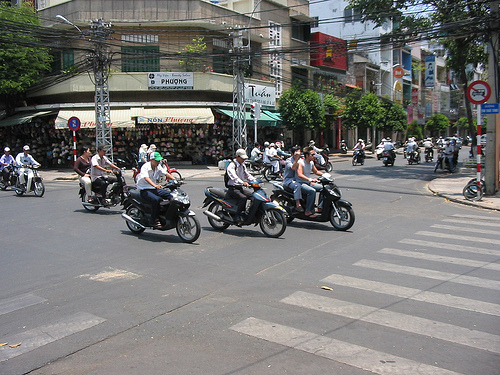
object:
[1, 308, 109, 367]
lines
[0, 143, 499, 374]
street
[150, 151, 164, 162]
hat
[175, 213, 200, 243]
wheel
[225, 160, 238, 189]
backpack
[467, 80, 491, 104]
sign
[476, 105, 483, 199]
pole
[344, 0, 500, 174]
tree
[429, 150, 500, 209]
sidewalk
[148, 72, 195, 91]
sign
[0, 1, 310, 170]
building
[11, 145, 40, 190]
motorcyclists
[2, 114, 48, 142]
merchandise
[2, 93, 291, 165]
store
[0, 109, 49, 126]
awnings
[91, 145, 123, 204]
biker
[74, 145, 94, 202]
passenger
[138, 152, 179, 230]
man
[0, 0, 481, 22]
wires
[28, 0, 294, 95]
structures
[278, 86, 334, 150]
trees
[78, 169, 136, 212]
motorcycle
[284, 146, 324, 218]
people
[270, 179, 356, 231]
motorcycle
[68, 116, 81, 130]
sign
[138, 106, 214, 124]
awning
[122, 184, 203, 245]
motorcycle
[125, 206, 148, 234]
wheel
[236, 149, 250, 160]
hat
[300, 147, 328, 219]
man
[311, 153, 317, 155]
sunglasses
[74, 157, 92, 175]
shirt